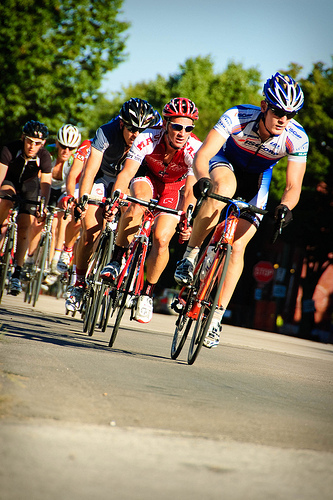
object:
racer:
[66, 95, 152, 308]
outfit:
[124, 127, 202, 219]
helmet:
[261, 69, 306, 114]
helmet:
[19, 119, 52, 138]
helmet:
[114, 92, 158, 127]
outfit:
[92, 116, 129, 193]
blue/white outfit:
[214, 105, 308, 224]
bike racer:
[112, 96, 203, 324]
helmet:
[161, 92, 199, 121]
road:
[254, 372, 331, 497]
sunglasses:
[167, 121, 194, 131]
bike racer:
[28, 124, 90, 302]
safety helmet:
[57, 116, 79, 153]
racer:
[173, 72, 309, 347]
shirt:
[213, 103, 309, 174]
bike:
[170, 180, 288, 364]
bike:
[108, 189, 192, 347]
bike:
[1, 191, 44, 300]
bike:
[24, 195, 70, 307]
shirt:
[0, 138, 54, 183]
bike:
[106, 184, 178, 354]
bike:
[69, 186, 108, 318]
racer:
[0, 113, 50, 285]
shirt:
[215, 101, 310, 190]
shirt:
[130, 128, 205, 219]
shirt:
[90, 113, 153, 189]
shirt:
[1, 138, 52, 215]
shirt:
[129, 129, 199, 191]